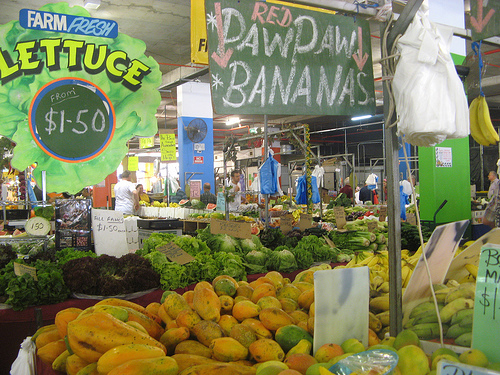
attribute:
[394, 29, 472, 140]
bags — plastic 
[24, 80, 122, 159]
price display — hand-written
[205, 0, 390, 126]
sign — chalk board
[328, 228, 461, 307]
bananas — bunch 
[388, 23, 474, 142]
pillar — white  , blue   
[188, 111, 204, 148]
fan — black    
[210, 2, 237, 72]
arrow — arrow pointing down   , red 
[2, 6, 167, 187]
pillar — white , green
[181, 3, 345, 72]
banner — yellow 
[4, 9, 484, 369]
market —  large farmers 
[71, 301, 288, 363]
squash — yellow 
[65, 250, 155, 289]
lettuce — green  , purple 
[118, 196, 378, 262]
table — long 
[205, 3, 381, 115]
sign — Red Paw Paw Bananas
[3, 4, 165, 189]
sign —  Farm Fresh Lettuce $1.50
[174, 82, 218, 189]
sign — white , large blue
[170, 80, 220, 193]
sign — white, blue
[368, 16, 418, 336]
pole — metal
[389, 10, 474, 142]
bags — white plastic 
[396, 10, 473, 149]
bags — white , Blue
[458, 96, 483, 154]
banana — yellow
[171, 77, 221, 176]
pillar — blue